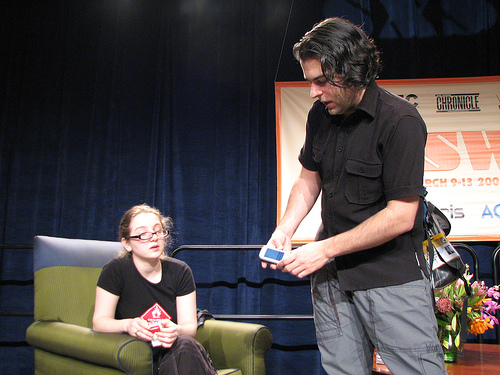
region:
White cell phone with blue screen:
[257, 244, 291, 265]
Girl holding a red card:
[91, 202, 217, 374]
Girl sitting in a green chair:
[91, 201, 223, 372]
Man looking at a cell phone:
[256, 15, 451, 373]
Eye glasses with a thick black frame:
[123, 228, 170, 242]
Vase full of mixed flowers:
[431, 260, 498, 365]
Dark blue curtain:
[0, 0, 498, 374]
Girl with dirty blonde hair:
[91, 202, 221, 374]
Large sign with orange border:
[273, 76, 499, 244]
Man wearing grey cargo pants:
[258, 15, 452, 374]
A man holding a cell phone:
[250, 21, 465, 374]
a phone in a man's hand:
[249, 236, 314, 280]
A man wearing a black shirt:
[257, 6, 457, 285]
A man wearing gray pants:
[289, 246, 445, 373]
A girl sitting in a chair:
[22, 203, 268, 373]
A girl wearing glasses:
[115, 202, 177, 259]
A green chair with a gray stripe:
[12, 218, 284, 373]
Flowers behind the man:
[435, 260, 498, 370]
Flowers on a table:
[428, 256, 498, 373]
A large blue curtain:
[32, 33, 251, 207]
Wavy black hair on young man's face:
[287, 18, 389, 121]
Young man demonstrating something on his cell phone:
[258, 16, 453, 373]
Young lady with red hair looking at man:
[90, 199, 221, 374]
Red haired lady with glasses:
[115, 201, 175, 264]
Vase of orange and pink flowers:
[426, 263, 496, 360]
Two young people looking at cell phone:
[84, 16, 447, 373]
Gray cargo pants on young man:
[298, 241, 451, 373]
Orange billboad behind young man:
[272, 75, 498, 245]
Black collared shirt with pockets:
[292, 76, 433, 288]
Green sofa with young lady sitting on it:
[26, 228, 277, 373]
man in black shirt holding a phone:
[258, 17, 446, 374]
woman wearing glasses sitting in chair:
[22, 203, 271, 373]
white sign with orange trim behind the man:
[274, 75, 497, 242]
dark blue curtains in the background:
[4, 3, 498, 374]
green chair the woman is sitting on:
[28, 236, 271, 374]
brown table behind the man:
[372, 344, 499, 374]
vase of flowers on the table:
[436, 260, 498, 362]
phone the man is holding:
[257, 241, 288, 263]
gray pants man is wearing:
[312, 280, 446, 374]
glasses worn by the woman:
[127, 229, 168, 240]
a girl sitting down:
[43, 173, 263, 374]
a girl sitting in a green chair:
[28, 193, 283, 370]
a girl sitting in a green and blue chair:
[15, 190, 271, 370]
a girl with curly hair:
[92, 186, 177, 296]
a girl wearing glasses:
[111, 193, 168, 270]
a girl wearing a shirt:
[100, 188, 235, 355]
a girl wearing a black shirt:
[90, 186, 227, 329]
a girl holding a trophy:
[91, 198, 226, 369]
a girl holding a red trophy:
[80, 169, 297, 346]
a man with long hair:
[246, 5, 443, 126]